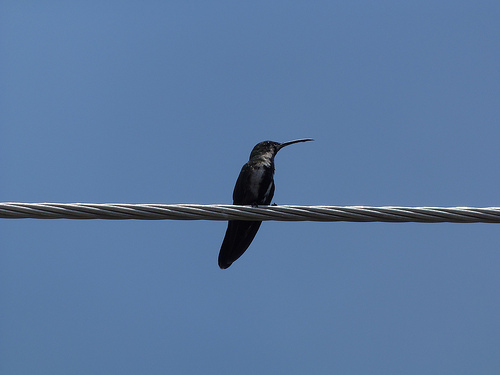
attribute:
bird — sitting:
[197, 125, 344, 318]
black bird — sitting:
[208, 131, 324, 298]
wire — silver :
[3, 205, 496, 224]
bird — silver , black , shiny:
[215, 137, 316, 276]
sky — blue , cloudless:
[5, 1, 491, 373]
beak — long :
[283, 137, 313, 147]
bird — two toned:
[222, 137, 311, 272]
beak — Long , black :
[277, 139, 311, 149]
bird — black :
[210, 140, 309, 271]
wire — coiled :
[5, 200, 494, 228]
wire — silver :
[2, 198, 496, 227]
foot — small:
[251, 193, 263, 213]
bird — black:
[210, 130, 322, 270]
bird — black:
[202, 133, 326, 275]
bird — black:
[213, 133, 313, 270]